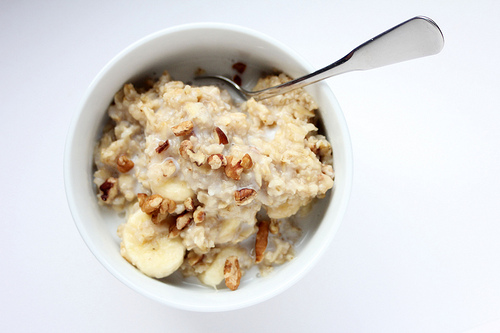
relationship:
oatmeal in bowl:
[98, 64, 328, 294] [64, 18, 353, 317]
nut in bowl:
[238, 151, 254, 174] [64, 18, 353, 317]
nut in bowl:
[233, 186, 252, 201] [64, 18, 353, 317]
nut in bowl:
[191, 190, 209, 206] [64, 18, 353, 317]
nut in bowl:
[157, 137, 169, 159] [64, 18, 353, 317]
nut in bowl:
[116, 152, 133, 171] [64, 18, 353, 317]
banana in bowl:
[121, 210, 188, 276] [64, 18, 353, 317]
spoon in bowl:
[187, 15, 449, 105] [64, 18, 353, 317]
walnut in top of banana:
[153, 193, 175, 224] [121, 210, 188, 276]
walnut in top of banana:
[139, 189, 162, 218] [121, 210, 188, 276]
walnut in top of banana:
[173, 208, 194, 233] [121, 210, 188, 276]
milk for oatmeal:
[105, 61, 312, 282] [98, 64, 328, 294]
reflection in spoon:
[255, 79, 304, 102] [187, 15, 449, 105]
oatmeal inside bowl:
[98, 64, 328, 294] [64, 18, 353, 317]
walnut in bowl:
[153, 193, 175, 224] [64, 18, 353, 317]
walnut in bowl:
[139, 189, 162, 218] [64, 18, 353, 317]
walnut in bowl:
[173, 208, 194, 233] [64, 18, 353, 317]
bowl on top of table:
[64, 18, 353, 317] [0, 2, 498, 333]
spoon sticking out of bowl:
[187, 15, 449, 105] [64, 18, 353, 317]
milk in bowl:
[105, 61, 312, 282] [64, 18, 353, 317]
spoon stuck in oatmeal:
[187, 15, 449, 105] [98, 64, 328, 294]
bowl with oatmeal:
[64, 18, 353, 317] [98, 64, 328, 294]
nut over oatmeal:
[233, 186, 252, 201] [98, 64, 328, 294]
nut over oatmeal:
[238, 151, 254, 174] [98, 64, 328, 294]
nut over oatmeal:
[157, 137, 169, 159] [98, 64, 328, 294]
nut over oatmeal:
[116, 152, 133, 171] [98, 64, 328, 294]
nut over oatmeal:
[191, 190, 209, 206] [98, 64, 328, 294]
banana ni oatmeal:
[121, 210, 188, 276] [98, 64, 328, 294]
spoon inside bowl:
[187, 15, 449, 105] [64, 18, 353, 317]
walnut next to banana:
[153, 193, 175, 224] [121, 210, 188, 276]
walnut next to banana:
[139, 189, 162, 218] [121, 210, 188, 276]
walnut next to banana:
[173, 208, 194, 233] [121, 210, 188, 276]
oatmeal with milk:
[98, 64, 328, 294] [105, 61, 312, 282]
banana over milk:
[121, 210, 188, 276] [105, 61, 312, 282]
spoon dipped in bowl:
[187, 15, 449, 105] [64, 18, 353, 317]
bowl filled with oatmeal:
[64, 18, 353, 317] [98, 64, 328, 294]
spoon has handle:
[187, 15, 449, 105] [255, 20, 448, 102]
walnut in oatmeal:
[153, 193, 175, 224] [98, 64, 328, 294]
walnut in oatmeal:
[139, 189, 162, 218] [98, 64, 328, 294]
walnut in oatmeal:
[173, 208, 194, 233] [98, 64, 328, 294]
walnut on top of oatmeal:
[153, 193, 175, 224] [98, 64, 328, 294]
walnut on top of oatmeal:
[173, 208, 194, 233] [98, 64, 328, 294]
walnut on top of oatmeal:
[139, 189, 162, 218] [98, 64, 328, 294]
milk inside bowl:
[105, 61, 312, 282] [64, 18, 353, 317]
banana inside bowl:
[121, 210, 188, 276] [64, 18, 353, 317]